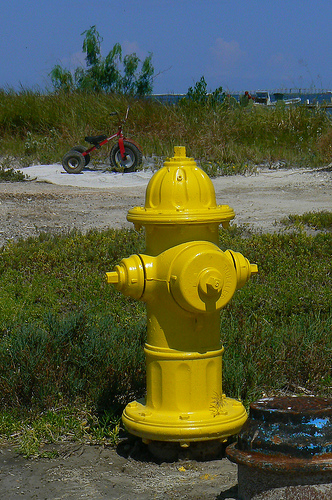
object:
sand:
[29, 167, 140, 190]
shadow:
[140, 223, 220, 245]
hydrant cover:
[123, 139, 235, 225]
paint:
[256, 408, 329, 451]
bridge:
[263, 87, 330, 101]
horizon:
[9, 85, 331, 105]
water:
[157, 90, 185, 98]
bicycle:
[56, 115, 148, 175]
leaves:
[85, 43, 97, 58]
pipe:
[138, 301, 228, 409]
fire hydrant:
[96, 140, 263, 461]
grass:
[0, 271, 102, 375]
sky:
[1, 2, 330, 91]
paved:
[5, 447, 240, 498]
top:
[220, 393, 331, 473]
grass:
[3, 85, 331, 165]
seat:
[80, 130, 108, 145]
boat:
[249, 89, 306, 104]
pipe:
[164, 238, 241, 320]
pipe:
[218, 242, 262, 291]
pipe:
[98, 249, 159, 302]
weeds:
[271, 285, 320, 377]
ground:
[0, 85, 332, 499]